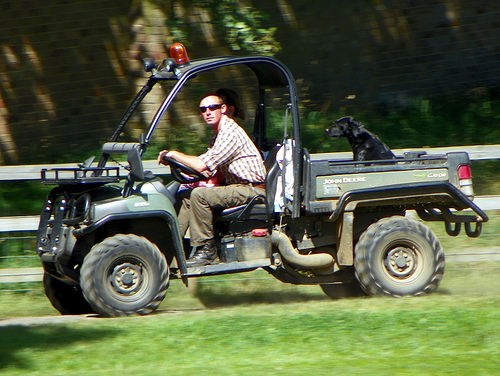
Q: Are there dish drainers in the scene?
A: No, there are no dish drainers.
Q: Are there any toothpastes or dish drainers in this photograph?
A: No, there are no dish drainers or toothpastes.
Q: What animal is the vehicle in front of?
A: The vehicle is in front of the dog.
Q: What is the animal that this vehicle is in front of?
A: The animal is a dog.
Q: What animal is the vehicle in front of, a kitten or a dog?
A: The vehicle is in front of a dog.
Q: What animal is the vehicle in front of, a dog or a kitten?
A: The vehicle is in front of a dog.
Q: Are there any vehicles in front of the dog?
A: Yes, there is a vehicle in front of the dog.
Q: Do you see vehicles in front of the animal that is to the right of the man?
A: Yes, there is a vehicle in front of the dog.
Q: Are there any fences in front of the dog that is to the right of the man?
A: No, there is a vehicle in front of the dog.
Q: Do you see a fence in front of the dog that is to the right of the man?
A: No, there is a vehicle in front of the dog.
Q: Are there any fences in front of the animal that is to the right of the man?
A: No, there is a vehicle in front of the dog.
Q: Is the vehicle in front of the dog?
A: Yes, the vehicle is in front of the dog.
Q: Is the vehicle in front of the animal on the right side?
A: Yes, the vehicle is in front of the dog.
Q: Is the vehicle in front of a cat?
A: No, the vehicle is in front of the dog.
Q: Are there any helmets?
A: No, there are no helmets.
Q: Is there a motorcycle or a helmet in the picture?
A: No, there are no helmets or motorcycles.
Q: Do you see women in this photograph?
A: No, there are no women.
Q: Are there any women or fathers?
A: No, there are no women or fathers.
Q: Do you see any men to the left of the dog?
A: Yes, there is a man to the left of the dog.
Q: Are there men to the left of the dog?
A: Yes, there is a man to the left of the dog.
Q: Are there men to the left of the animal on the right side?
A: Yes, there is a man to the left of the dog.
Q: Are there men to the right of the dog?
A: No, the man is to the left of the dog.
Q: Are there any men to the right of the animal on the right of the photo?
A: No, the man is to the left of the dog.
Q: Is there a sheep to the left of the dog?
A: No, there is a man to the left of the dog.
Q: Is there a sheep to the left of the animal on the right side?
A: No, there is a man to the left of the dog.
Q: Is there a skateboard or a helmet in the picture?
A: No, there are no helmets or skateboards.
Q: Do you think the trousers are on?
A: Yes, the trousers are on.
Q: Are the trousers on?
A: Yes, the trousers are on.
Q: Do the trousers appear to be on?
A: Yes, the trousers are on.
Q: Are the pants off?
A: No, the pants are on.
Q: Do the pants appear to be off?
A: No, the pants are on.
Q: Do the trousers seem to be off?
A: No, the trousers are on.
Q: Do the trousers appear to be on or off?
A: The trousers are on.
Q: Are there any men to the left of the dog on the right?
A: Yes, there is a man to the left of the dog.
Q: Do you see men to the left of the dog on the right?
A: Yes, there is a man to the left of the dog.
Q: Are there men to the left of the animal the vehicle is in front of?
A: Yes, there is a man to the left of the dog.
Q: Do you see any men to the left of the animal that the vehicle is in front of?
A: Yes, there is a man to the left of the dog.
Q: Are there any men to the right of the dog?
A: No, the man is to the left of the dog.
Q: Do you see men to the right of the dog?
A: No, the man is to the left of the dog.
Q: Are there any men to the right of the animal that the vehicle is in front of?
A: No, the man is to the left of the dog.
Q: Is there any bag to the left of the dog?
A: No, there is a man to the left of the dog.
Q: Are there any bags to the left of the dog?
A: No, there is a man to the left of the dog.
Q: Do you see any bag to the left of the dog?
A: No, there is a man to the left of the dog.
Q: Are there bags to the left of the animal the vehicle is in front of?
A: No, there is a man to the left of the dog.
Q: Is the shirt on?
A: Yes, the shirt is on.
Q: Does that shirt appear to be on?
A: Yes, the shirt is on.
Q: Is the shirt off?
A: No, the shirt is on.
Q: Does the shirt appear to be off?
A: No, the shirt is on.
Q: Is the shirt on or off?
A: The shirt is on.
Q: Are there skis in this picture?
A: No, there are no skis.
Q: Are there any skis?
A: No, there are no skis.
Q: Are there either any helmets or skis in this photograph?
A: No, there are no skis or helmets.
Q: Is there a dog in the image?
A: Yes, there is a dog.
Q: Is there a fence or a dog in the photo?
A: Yes, there is a dog.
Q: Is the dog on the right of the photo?
A: Yes, the dog is on the right of the image.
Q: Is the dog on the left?
A: No, the dog is on the right of the image.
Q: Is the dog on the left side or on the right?
A: The dog is on the right of the image.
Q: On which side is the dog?
A: The dog is on the right of the image.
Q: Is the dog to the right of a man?
A: Yes, the dog is to the right of a man.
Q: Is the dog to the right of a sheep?
A: No, the dog is to the right of a man.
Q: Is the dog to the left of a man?
A: No, the dog is to the right of a man.